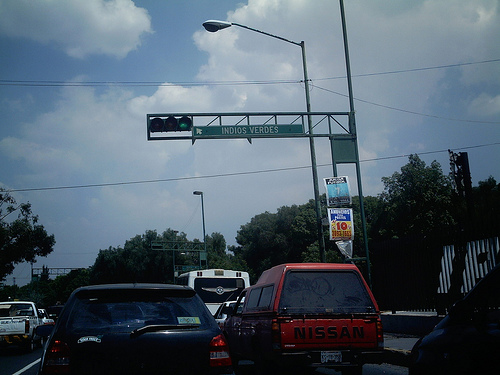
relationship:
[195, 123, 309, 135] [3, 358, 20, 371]
street sign over street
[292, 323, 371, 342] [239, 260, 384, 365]
logo painted on car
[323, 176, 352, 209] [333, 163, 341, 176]
advertisement posted on pole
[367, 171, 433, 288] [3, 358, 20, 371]
tree next to street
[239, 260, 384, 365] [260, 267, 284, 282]
car has canopy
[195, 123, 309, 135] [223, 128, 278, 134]
street sign has lettering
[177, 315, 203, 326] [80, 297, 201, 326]
sticker on window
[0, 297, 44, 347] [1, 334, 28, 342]
truck has bumper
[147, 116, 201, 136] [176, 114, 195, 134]
traffic light with light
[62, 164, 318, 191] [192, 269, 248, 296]
power line over bus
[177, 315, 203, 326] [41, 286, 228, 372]
sticker pasted on car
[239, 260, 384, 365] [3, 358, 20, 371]
car driving on street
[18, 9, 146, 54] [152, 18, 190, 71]
cloud floating in sky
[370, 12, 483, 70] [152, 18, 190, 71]
cloud hovering in sky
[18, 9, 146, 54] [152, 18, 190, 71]
cloud in sky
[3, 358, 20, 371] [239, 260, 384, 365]
street under car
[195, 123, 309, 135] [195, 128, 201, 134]
street sign has arrow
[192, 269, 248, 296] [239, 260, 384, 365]
bus in front of car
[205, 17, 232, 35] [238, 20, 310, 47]
light mounted on pole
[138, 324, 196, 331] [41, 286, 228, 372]
wiper on car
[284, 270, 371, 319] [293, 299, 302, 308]
window covered in dust